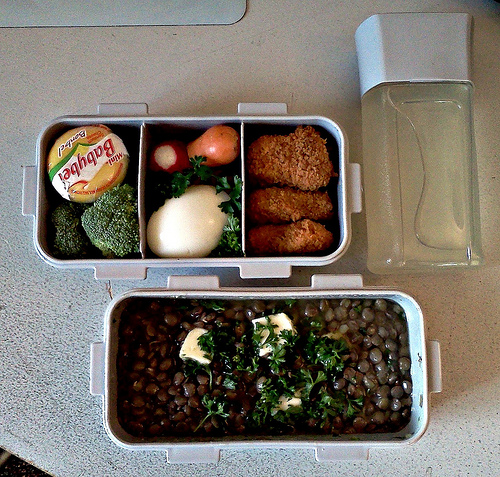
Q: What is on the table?
A: Containers.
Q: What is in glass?
A: Water.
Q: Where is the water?
A: Glass container.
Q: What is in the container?
A: Nuggets.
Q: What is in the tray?
A: Boiled egg.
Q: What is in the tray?
A: Broccoli.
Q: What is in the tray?
A: Beans.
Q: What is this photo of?
A: A table.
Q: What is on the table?
A: Food.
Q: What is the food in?
A: Containers.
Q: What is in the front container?
A: Beans.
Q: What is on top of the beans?
A: Parsley.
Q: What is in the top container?
A: Chicken.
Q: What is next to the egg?
A: Broccoli.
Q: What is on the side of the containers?
A: Water.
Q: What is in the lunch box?
A: Chicken nuggets.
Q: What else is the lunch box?
A: Lentils.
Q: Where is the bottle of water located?
A: On the table.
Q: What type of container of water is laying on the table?
A: Clear.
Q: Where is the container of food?
A: On the table.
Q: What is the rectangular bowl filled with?
A: Beans.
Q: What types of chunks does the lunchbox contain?
A: Breaded meat.